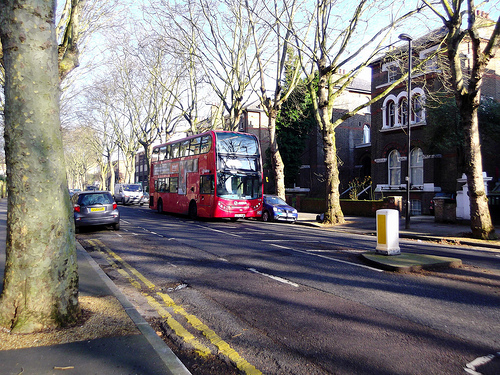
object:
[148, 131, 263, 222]
bus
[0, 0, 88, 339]
tree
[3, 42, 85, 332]
trunk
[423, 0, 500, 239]
tree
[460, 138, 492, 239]
trunk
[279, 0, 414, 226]
tree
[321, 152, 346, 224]
trunk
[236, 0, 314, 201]
tree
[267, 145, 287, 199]
trunk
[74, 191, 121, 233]
car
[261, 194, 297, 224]
car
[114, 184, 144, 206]
suv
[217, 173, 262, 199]
windshield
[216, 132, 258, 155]
windshield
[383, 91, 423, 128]
windows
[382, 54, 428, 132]
trim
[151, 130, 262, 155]
top deck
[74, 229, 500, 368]
street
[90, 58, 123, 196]
tree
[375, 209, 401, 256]
pole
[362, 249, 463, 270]
ground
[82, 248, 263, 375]
cross lines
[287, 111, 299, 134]
leaves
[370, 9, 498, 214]
building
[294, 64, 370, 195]
building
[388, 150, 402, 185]
window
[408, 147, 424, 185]
window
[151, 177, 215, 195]
lower level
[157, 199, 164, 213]
tires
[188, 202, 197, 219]
tires